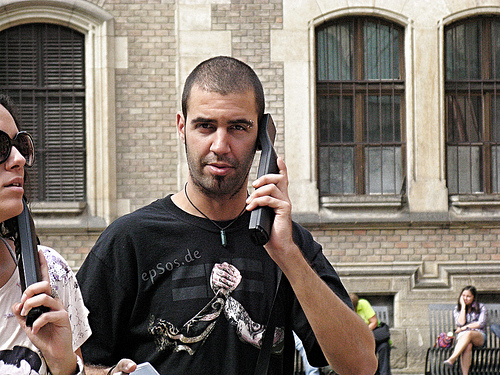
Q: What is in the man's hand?
A: Phone.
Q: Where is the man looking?
A: At camera.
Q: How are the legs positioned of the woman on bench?
A: Crossed.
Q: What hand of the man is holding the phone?
A: Left hand.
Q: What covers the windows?
A: Brown bars.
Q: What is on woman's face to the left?
A: Sunglasses.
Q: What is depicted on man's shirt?
A: Arm wrestling.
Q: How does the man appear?
A: Focused.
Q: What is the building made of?
A: Bricks.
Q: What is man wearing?
A: A shirt.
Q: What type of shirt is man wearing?
A: T-shirt.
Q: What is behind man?
A: A building.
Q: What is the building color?
A: Tan.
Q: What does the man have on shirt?
A: A design.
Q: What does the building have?
A: Windows.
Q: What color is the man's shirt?
A: Black.